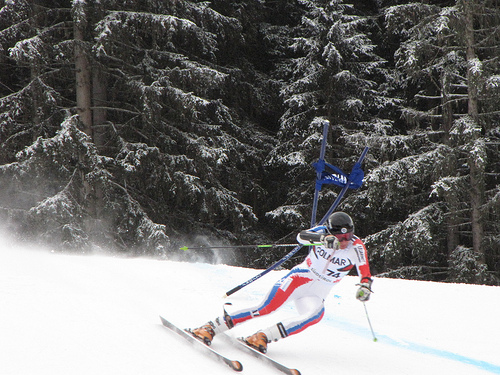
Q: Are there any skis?
A: Yes, there are skis.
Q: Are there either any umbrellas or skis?
A: Yes, there are skis.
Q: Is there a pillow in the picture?
A: No, there are no pillows.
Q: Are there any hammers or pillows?
A: No, there are no pillows or hammers.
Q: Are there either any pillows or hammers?
A: No, there are no pillows or hammers.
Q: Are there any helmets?
A: Yes, there is a helmet.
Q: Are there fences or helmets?
A: Yes, there is a helmet.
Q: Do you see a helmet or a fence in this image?
A: Yes, there is a helmet.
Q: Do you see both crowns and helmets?
A: No, there is a helmet but no crowns.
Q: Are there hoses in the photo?
A: No, there are no hoses.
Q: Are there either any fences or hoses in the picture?
A: No, there are no hoses or fences.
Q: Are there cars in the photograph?
A: No, there are no cars.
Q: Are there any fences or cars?
A: No, there are no cars or fences.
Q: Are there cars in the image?
A: No, there are no cars.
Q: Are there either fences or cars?
A: No, there are no cars or fences.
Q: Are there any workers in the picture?
A: No, there are no workers.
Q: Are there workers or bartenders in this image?
A: No, there are no workers or bartenders.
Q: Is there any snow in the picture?
A: Yes, there is snow.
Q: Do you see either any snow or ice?
A: Yes, there is snow.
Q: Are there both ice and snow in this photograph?
A: No, there is snow but no ice.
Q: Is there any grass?
A: No, there is no grass.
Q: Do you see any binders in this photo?
A: No, there are no binders.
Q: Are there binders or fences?
A: No, there are no binders or fences.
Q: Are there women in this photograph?
A: No, there are no women.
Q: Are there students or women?
A: No, there are no women or students.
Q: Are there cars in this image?
A: No, there are no cars.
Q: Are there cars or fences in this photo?
A: No, there are no cars or fences.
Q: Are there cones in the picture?
A: No, there are no cones.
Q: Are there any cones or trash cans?
A: No, there are no cones or trash cans.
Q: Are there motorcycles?
A: No, there are no motorcycles.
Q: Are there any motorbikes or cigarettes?
A: No, there are no motorbikes or cigarettes.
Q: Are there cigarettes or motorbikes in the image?
A: No, there are no motorbikes or cigarettes.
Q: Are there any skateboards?
A: No, there are no skateboards.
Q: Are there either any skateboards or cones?
A: No, there are no skateboards or cones.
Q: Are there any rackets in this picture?
A: No, there are no rackets.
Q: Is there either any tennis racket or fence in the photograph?
A: No, there are no rackets or fences.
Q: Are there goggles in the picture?
A: Yes, there are goggles.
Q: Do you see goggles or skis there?
A: Yes, there are goggles.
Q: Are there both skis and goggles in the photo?
A: Yes, there are both goggles and skis.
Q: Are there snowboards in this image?
A: No, there are no snowboards.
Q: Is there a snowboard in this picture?
A: No, there are no snowboards.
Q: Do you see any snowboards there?
A: No, there are no snowboards.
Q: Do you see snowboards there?
A: No, there are no snowboards.